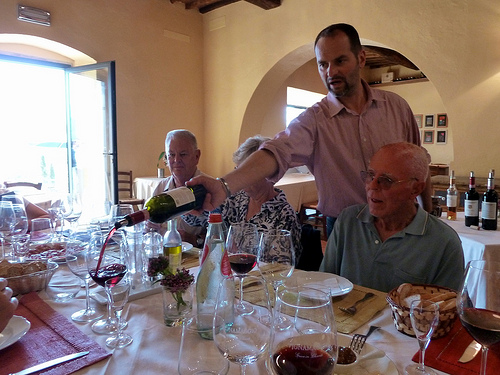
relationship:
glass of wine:
[262, 282, 338, 369] [227, 254, 254, 274]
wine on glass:
[88, 227, 126, 286] [82, 237, 143, 308]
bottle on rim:
[148, 190, 203, 230] [100, 221, 132, 242]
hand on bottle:
[176, 163, 246, 209] [148, 190, 203, 230]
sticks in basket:
[393, 280, 460, 308] [391, 282, 464, 339]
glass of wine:
[90, 230, 130, 335] [88, 264, 129, 282]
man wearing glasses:
[330, 142, 464, 280] [344, 155, 413, 201]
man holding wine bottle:
[204, 25, 426, 281] [122, 172, 217, 242]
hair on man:
[162, 129, 197, 145] [330, 142, 472, 302]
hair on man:
[315, 26, 363, 47] [246, 16, 426, 281]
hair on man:
[384, 141, 429, 174] [330, 142, 472, 302]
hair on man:
[235, 141, 265, 160] [330, 142, 472, 302]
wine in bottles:
[90, 210, 146, 235] [82, 177, 302, 315]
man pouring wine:
[330, 142, 464, 280] [88, 227, 126, 286]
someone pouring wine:
[183, 130, 299, 264] [88, 227, 126, 286]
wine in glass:
[227, 254, 254, 274] [217, 215, 310, 307]